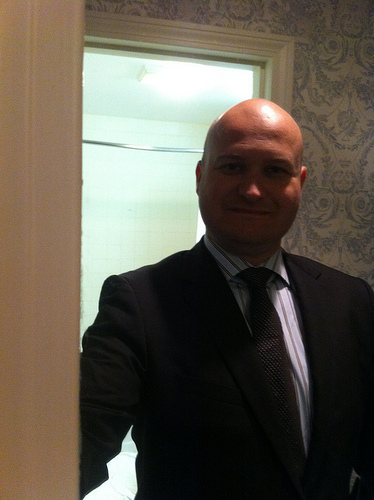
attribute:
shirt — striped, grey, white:
[203, 236, 310, 468]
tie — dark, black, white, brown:
[236, 265, 303, 483]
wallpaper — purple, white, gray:
[86, 0, 373, 292]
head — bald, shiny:
[205, 96, 300, 156]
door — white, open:
[0, 0, 82, 499]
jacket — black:
[79, 237, 374, 499]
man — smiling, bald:
[79, 95, 373, 500]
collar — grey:
[205, 235, 291, 286]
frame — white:
[87, 12, 294, 65]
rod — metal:
[80, 137, 205, 155]